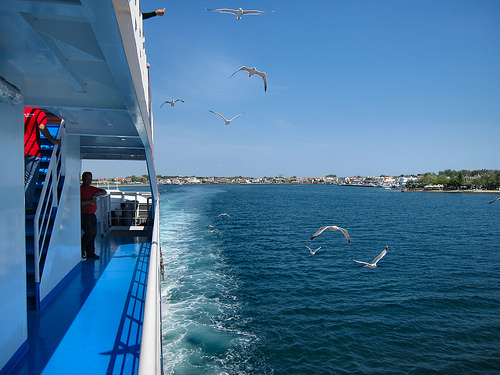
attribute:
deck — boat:
[7, 192, 163, 371]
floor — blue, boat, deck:
[2, 220, 150, 373]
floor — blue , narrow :
[56, 190, 163, 364]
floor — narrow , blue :
[42, 186, 151, 371]